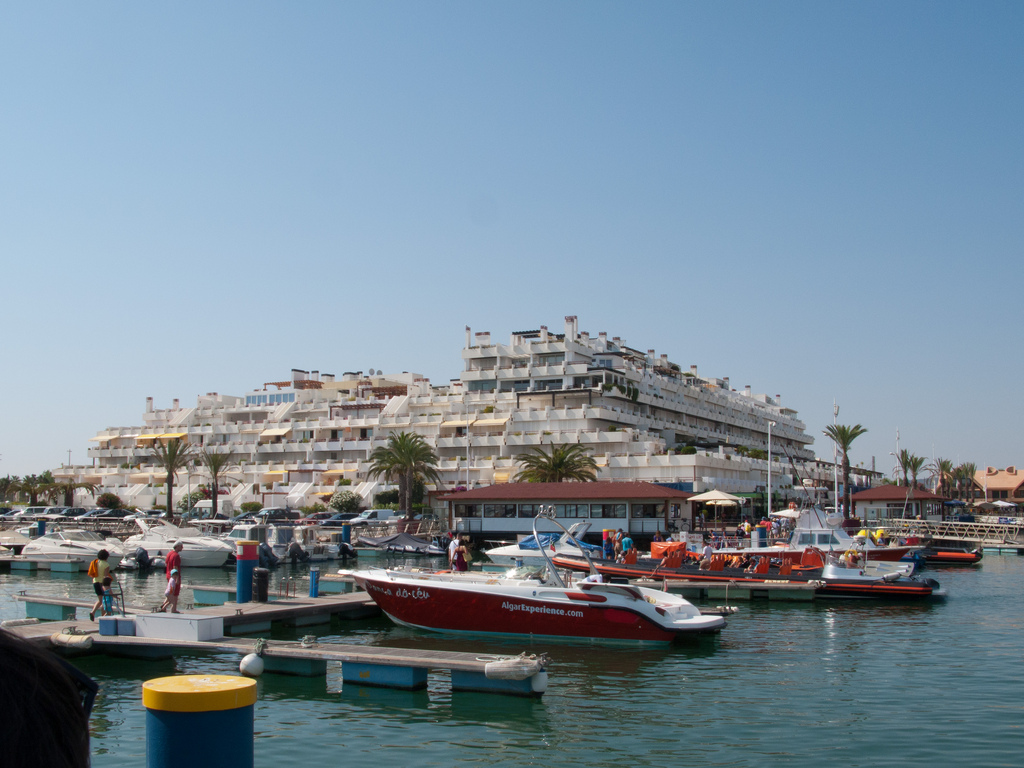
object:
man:
[162, 536, 189, 613]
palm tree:
[822, 419, 868, 525]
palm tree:
[514, 436, 607, 487]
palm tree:
[389, 432, 436, 517]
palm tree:
[197, 448, 236, 513]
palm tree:
[150, 436, 193, 522]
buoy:
[235, 649, 266, 677]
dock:
[2, 575, 550, 699]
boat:
[121, 515, 231, 572]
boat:
[24, 531, 122, 572]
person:
[90, 549, 122, 613]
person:
[162, 570, 179, 613]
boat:
[337, 557, 744, 648]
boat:
[714, 510, 927, 581]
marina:
[0, 515, 1022, 765]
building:
[50, 315, 882, 547]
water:
[0, 546, 1022, 763]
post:
[137, 665, 265, 765]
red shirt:
[164, 551, 183, 578]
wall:
[443, 513, 686, 537]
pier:
[24, 422, 913, 708]